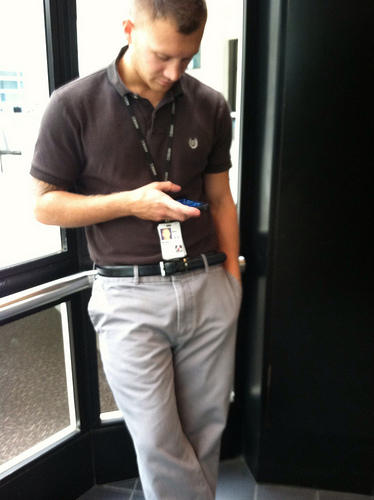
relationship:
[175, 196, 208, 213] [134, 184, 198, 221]
cell phone in hand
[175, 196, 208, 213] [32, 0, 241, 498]
cell phone in hand of man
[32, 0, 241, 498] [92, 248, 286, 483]
man wearing pants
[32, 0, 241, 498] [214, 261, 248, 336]
man holding hand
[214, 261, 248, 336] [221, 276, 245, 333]
hand in pocket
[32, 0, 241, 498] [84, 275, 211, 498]
man crossing leg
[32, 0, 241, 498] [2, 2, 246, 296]
man standing near window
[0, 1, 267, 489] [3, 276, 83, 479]
window near building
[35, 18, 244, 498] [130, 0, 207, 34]
boy has brown hair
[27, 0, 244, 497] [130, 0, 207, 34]
boy has brown hair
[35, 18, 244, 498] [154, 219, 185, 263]
boy wearing lanyard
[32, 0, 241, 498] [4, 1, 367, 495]
man standing inside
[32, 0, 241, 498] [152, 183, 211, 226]
man on a phone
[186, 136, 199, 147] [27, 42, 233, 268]
logo on polo shirt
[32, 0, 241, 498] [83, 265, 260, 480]
man wearing khakies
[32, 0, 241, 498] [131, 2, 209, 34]
man with hair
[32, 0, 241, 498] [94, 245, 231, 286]
man wearing belt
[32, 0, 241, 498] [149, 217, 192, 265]
man wearing badge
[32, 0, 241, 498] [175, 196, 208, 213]
man holding cell phone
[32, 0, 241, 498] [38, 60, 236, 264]
man wearing shirt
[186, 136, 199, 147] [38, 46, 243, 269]
logo on shirt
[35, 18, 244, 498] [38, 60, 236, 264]
boy has shirt